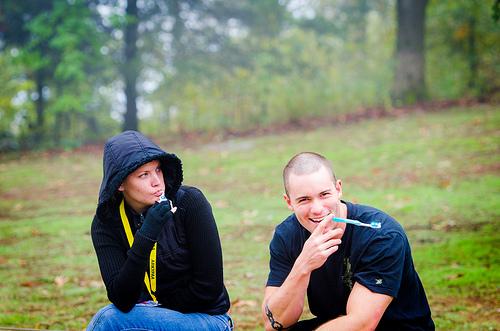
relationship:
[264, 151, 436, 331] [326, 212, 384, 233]
man holding tooth brush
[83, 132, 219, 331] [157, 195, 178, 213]
girl holding tooth brush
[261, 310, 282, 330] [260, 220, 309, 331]
tattoo on arm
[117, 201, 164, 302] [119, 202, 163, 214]
lanyard hanging around neck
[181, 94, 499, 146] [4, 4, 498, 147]
leaves are laying along tree line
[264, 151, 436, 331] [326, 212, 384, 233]
guy holding tooth brush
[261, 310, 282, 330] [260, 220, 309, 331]
tattoo around arm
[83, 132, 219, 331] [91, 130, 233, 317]
person wearing a hoodie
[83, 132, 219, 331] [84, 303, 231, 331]
person wearing jeans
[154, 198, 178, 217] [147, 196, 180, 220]
glove on hand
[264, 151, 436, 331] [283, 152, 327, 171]
man has short hair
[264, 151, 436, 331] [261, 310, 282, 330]
man has a tattoo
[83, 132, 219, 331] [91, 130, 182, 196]
woman wearing a hood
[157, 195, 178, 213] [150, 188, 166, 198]
tooth brush in a womans mouth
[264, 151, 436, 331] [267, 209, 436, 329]
man wearing a blue shirt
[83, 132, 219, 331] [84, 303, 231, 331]
woman wearing blue jeans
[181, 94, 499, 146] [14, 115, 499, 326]
leaves are on ground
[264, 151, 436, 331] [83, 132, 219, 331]
man sitting next to a woman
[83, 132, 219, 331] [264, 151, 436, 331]
woman sitting next to a man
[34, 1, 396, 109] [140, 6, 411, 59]
sky peeking through branches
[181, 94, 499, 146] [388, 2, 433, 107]
leaves are off tree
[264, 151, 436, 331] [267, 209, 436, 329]
shirt wearing a blue shirt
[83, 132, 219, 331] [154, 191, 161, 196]
lady brushing her teeth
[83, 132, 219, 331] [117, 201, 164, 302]
woman wearing a yellow necklace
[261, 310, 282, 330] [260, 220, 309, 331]
tattoo on mans arm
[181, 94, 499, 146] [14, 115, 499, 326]
leaves are on grass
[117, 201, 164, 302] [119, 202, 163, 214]
string around a womans neck